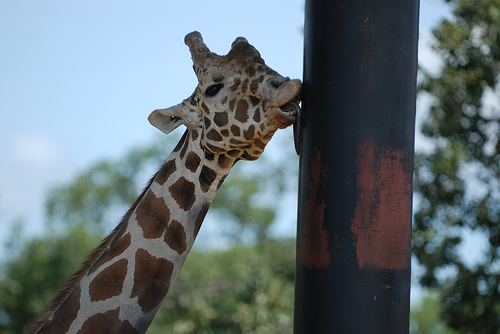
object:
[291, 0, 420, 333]
black pole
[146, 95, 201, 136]
ear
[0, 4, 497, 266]
sky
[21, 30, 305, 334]
giraffe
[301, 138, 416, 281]
spots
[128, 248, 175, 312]
brown spots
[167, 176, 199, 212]
brown spot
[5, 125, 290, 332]
trees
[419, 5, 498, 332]
tree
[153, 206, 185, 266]
spot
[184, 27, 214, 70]
horn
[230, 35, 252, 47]
horn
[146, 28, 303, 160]
head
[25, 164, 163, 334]
hair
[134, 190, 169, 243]
spot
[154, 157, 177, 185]
spot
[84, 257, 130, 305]
spot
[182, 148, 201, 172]
spot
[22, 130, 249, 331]
giraffe's neck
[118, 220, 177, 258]
middle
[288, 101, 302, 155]
tongue